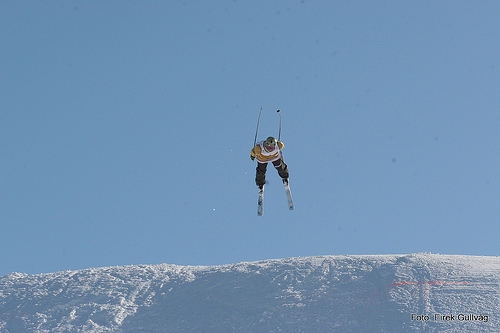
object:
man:
[250, 135, 291, 193]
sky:
[0, 1, 499, 265]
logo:
[409, 312, 491, 322]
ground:
[49, 272, 453, 330]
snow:
[42, 263, 259, 332]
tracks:
[81, 274, 357, 315]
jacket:
[250, 141, 285, 164]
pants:
[254, 157, 290, 186]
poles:
[278, 104, 282, 142]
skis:
[255, 192, 265, 216]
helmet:
[264, 136, 276, 148]